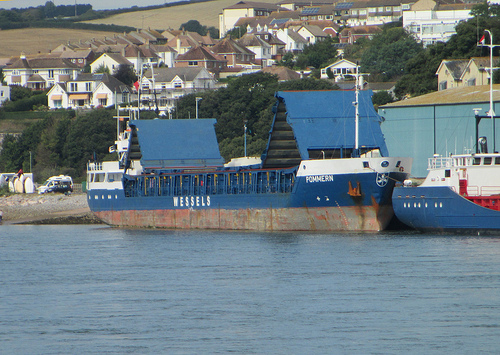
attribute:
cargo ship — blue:
[82, 115, 409, 233]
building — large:
[401, 7, 483, 52]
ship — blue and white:
[79, 150, 420, 235]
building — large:
[21, 54, 178, 129]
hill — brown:
[1, 2, 248, 53]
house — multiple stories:
[40, 71, 138, 119]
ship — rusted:
[57, 88, 397, 249]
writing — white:
[165, 192, 218, 208]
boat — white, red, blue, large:
[78, 51, 411, 236]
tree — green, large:
[66, 109, 128, 180]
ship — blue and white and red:
[390, 150, 499, 232]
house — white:
[45, 72, 130, 109]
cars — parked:
[4, 166, 94, 193]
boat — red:
[388, 148, 499, 249]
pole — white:
[482, 36, 498, 106]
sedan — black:
[45, 180, 71, 195]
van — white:
[33, 172, 73, 196]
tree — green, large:
[362, 27, 427, 79]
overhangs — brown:
[41, 65, 99, 92]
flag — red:
[473, 25, 489, 48]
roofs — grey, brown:
[1, 27, 213, 56]